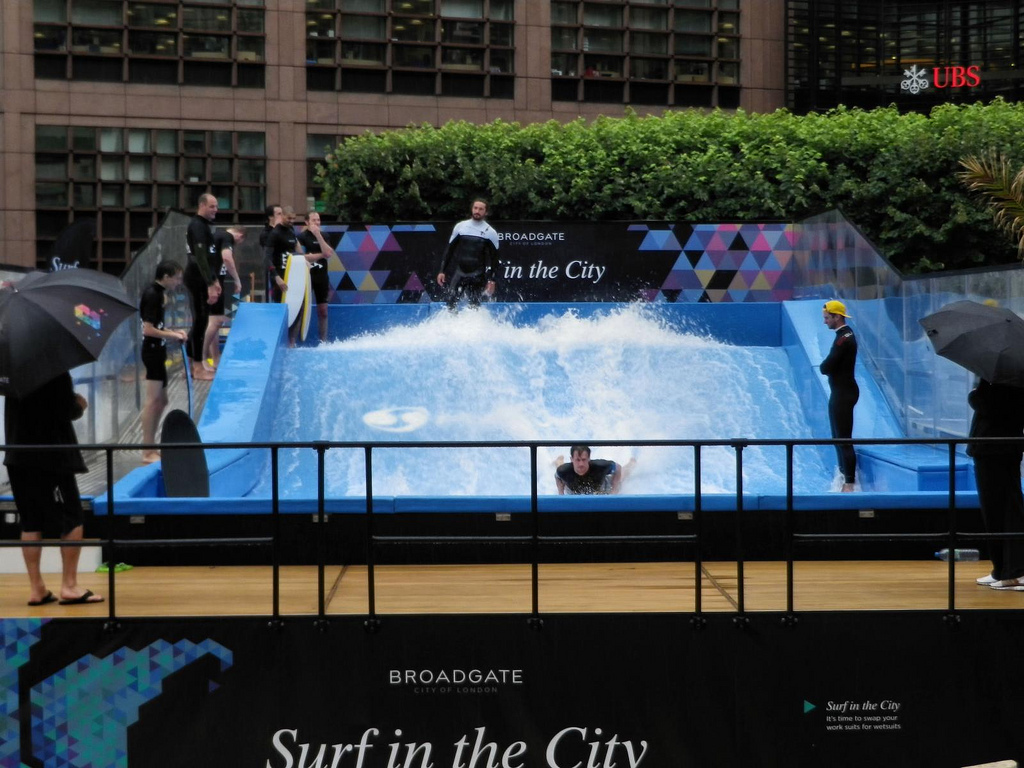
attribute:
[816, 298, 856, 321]
cap — yellow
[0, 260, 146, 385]
umbrella — black 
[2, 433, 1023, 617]
railing — black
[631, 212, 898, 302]
pattern — diamond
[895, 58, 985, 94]
name — white, red 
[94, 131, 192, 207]
blinds — white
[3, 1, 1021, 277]
building — huge 